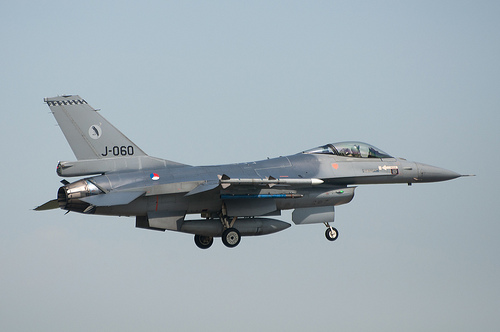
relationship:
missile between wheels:
[167, 217, 292, 237] [185, 226, 237, 252]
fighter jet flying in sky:
[36, 91, 479, 249] [2, 2, 498, 329]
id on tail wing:
[100, 143, 135, 158] [43, 94, 146, 159]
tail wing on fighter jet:
[43, 94, 146, 159] [31, 94, 479, 248]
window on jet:
[304, 141, 394, 159] [30, 108, 474, 245]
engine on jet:
[35, 181, 101, 221] [28, 83, 485, 266]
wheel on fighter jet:
[222, 228, 241, 248] [31, 94, 479, 248]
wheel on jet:
[196, 224, 260, 266] [54, 96, 496, 254]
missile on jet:
[208, 162, 339, 205] [26, 65, 487, 257]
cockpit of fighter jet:
[302, 141, 394, 158] [31, 94, 479, 248]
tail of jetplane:
[41, 92, 142, 172] [28, 93, 475, 248]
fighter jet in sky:
[31, 94, 479, 248] [2, 2, 498, 329]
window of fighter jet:
[307, 141, 391, 160] [31, 94, 479, 248]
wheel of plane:
[222, 228, 241, 248] [28, 64, 499, 267]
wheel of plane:
[327, 227, 341, 239] [28, 64, 499, 267]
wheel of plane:
[222, 228, 241, 248] [26, 92, 478, 252]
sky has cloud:
[2, 2, 498, 329] [1, 235, 498, 326]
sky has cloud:
[2, 2, 498, 329] [336, 139, 498, 246]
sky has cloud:
[2, 2, 498, 329] [1, 2, 488, 162]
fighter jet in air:
[31, 94, 479, 248] [44, 15, 472, 41]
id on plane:
[102, 145, 134, 156] [28, 74, 486, 249]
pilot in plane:
[300, 119, 398, 174] [26, 92, 478, 252]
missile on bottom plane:
[162, 218, 292, 232] [29, 81, 481, 236]